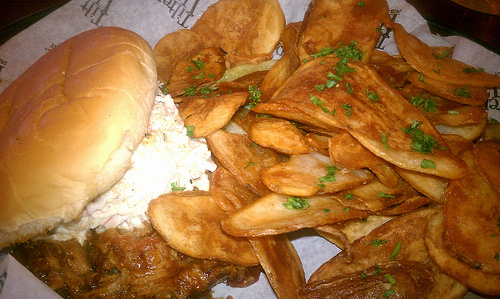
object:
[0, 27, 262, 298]
hamburger bun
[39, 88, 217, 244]
white chicken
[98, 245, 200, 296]
brown chicken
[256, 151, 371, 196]
potato slices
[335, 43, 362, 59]
green season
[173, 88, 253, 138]
fries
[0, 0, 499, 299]
wrap paper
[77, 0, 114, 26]
writing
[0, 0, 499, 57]
background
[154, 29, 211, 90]
cheese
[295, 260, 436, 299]
bacon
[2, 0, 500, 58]
plate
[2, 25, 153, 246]
bun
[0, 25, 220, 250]
hamburger